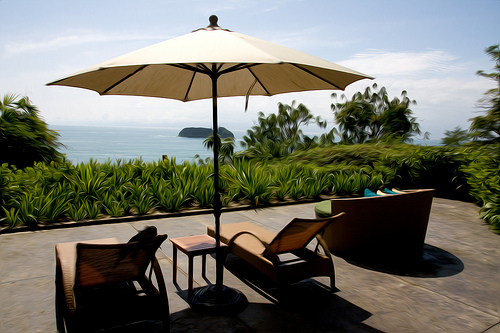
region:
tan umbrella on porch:
[64, 11, 361, 115]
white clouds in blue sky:
[410, 56, 454, 87]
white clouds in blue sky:
[350, 11, 395, 42]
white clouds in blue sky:
[14, 11, 52, 42]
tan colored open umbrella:
[51, 28, 359, 98]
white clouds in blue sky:
[11, 15, 42, 32]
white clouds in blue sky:
[410, 12, 471, 53]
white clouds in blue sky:
[341, 13, 386, 45]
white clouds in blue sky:
[72, 105, 102, 126]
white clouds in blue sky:
[284, 9, 332, 27]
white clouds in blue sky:
[361, 13, 419, 53]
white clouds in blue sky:
[400, 36, 442, 78]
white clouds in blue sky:
[37, 23, 99, 44]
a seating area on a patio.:
[17, 10, 498, 325]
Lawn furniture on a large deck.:
[32, 10, 452, 321]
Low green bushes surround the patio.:
[5, 136, 496, 223]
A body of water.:
[15, 117, 461, 169]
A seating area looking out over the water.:
[52, 172, 453, 324]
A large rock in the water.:
[175, 125, 237, 142]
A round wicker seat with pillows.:
[304, 173, 453, 259]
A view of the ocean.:
[6, 112, 497, 198]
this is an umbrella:
[28, 4, 374, 151]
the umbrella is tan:
[20, 15, 391, 137]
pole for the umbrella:
[173, 71, 246, 324]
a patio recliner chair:
[202, 187, 344, 304]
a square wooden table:
[166, 204, 226, 291]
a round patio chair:
[292, 157, 439, 264]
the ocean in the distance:
[22, 86, 364, 184]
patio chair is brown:
[197, 186, 351, 293]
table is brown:
[162, 205, 239, 311]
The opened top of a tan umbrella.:
[42, 26, 375, 105]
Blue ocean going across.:
[47, 121, 494, 163]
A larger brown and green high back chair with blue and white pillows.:
[312, 186, 434, 263]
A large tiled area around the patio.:
[0, 195, 499, 332]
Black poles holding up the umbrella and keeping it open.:
[170, 63, 257, 317]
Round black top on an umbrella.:
[208, 15, 217, 26]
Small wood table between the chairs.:
[167, 232, 228, 301]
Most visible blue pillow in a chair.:
[363, 187, 381, 199]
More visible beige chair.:
[206, 210, 347, 297]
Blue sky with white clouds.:
[0, 2, 498, 129]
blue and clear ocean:
[40, 123, 483, 165]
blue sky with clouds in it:
[1, 3, 499, 137]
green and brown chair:
[318, 184, 435, 258]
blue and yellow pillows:
[361, 185, 406, 200]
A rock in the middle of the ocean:
[114, 108, 251, 165]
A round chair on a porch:
[301, 165, 453, 250]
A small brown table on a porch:
[147, 223, 227, 300]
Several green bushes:
[300, 77, 417, 194]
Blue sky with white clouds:
[327, 17, 448, 99]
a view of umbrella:
[86, 43, 387, 130]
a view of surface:
[381, 291, 463, 327]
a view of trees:
[118, 125, 242, 186]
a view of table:
[171, 221, 236, 312]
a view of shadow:
[410, 250, 462, 285]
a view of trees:
[336, 103, 438, 144]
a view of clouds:
[394, 51, 479, 119]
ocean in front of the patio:
[47, 112, 453, 173]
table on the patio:
[169, 229, 221, 286]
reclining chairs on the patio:
[43, 197, 341, 317]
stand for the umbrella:
[204, 75, 253, 310]